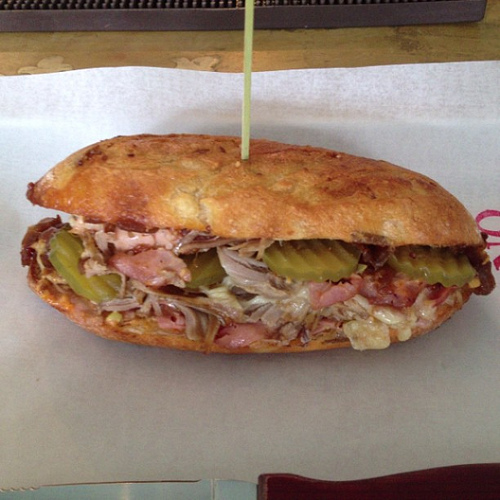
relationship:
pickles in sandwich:
[36, 229, 485, 301] [20, 132, 492, 362]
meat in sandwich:
[21, 202, 483, 346] [20, 132, 492, 362]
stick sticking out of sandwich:
[239, 0, 256, 163] [20, 132, 492, 362]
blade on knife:
[0, 477, 257, 499] [0, 460, 500, 498]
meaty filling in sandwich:
[26, 212, 492, 341] [20, 132, 492, 362]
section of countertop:
[275, 404, 442, 458] [0, 364, 492, 469]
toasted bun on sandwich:
[24, 132, 484, 248] [20, 132, 492, 362]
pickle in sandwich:
[37, 221, 119, 311] [266, 244, 358, 284]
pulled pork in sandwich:
[310, 277, 427, 317] [20, 132, 492, 362]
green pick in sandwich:
[238, 0, 259, 162] [20, 132, 492, 362]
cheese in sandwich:
[363, 299, 436, 346] [26, 146, 481, 348]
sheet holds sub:
[364, 80, 486, 150] [113, 185, 345, 355]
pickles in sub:
[266, 245, 471, 286] [49, 108, 483, 342]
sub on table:
[22, 133, 475, 348] [6, 25, 484, 479]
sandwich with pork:
[42, 68, 428, 358] [316, 258, 446, 330]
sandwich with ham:
[42, 68, 428, 358] [301, 269, 365, 309]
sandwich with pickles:
[42, 68, 428, 358] [55, 221, 133, 309]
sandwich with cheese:
[42, 68, 428, 358] [68, 219, 196, 323]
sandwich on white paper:
[20, 132, 492, 362] [52, 356, 367, 460]